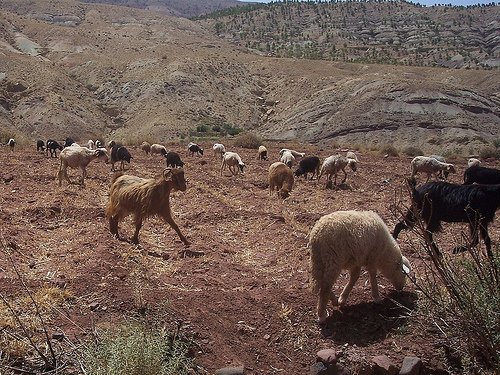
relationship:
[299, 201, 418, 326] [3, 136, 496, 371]
sheep grazing on hill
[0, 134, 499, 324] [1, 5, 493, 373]
goats grazing on mountain valley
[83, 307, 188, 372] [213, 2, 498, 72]
shrub growing on mountain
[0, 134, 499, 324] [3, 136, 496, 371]
goats grazing on hill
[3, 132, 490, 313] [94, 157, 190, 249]
herd of goat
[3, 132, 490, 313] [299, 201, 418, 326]
herd of sheep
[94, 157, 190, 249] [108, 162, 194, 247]
goat with horns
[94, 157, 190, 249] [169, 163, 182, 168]
goat with horns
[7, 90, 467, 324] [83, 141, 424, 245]
field of goats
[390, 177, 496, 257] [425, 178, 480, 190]
goat has ridge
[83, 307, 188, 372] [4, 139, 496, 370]
shrub on ground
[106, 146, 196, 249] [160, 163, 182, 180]
sheep has horns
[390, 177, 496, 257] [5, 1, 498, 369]
goat in field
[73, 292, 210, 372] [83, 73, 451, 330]
bush in field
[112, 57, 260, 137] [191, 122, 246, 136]
hill has patch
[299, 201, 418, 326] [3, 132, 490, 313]
sheep in herd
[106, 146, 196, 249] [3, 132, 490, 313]
sheep in herd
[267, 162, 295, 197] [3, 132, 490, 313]
sheep in herd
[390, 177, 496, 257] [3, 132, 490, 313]
goat in herd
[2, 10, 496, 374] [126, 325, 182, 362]
hill with no plant